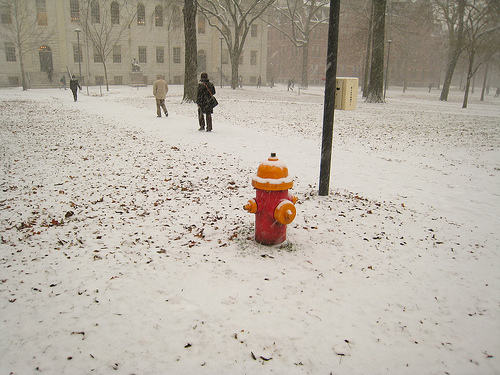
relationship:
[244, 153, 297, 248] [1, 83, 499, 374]
hydrant on top of snow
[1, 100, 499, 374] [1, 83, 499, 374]
leaves on top of snow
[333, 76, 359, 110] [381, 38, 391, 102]
can next to pole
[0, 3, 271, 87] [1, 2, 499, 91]
building inside of background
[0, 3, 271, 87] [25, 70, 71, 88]
building with steps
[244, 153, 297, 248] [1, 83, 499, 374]
hydrant covered in snow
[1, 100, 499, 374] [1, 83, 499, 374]
leaves surrounding snow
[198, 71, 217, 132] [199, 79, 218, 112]
man carrying bag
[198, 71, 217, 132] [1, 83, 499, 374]
man walking on snow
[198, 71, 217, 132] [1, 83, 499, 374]
man covered in snow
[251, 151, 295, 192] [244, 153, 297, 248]
top above hydrant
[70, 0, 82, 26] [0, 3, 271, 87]
window in front of building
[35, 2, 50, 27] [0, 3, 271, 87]
window in front of building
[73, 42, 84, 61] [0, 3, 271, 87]
window in front of building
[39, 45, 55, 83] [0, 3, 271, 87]
door in front of building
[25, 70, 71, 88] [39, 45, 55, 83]
steps in front of door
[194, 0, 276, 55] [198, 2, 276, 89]
branches apart of tree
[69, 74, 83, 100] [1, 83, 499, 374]
man walking on snow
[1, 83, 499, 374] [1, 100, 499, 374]
snow surrounds leaves